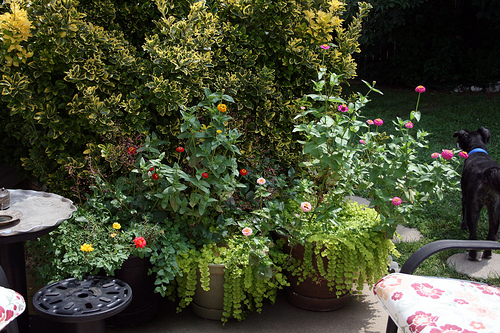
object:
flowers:
[430, 148, 469, 161]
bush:
[358, 84, 470, 239]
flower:
[133, 236, 147, 249]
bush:
[36, 184, 191, 295]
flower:
[80, 243, 95, 253]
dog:
[452, 126, 500, 261]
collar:
[467, 148, 490, 156]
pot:
[106, 254, 162, 333]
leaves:
[0, 0, 375, 174]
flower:
[410, 281, 445, 299]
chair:
[372, 237, 497, 333]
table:
[0, 189, 78, 331]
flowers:
[366, 117, 383, 125]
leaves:
[148, 228, 292, 328]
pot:
[282, 235, 355, 312]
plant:
[278, 191, 402, 302]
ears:
[452, 125, 491, 140]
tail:
[485, 167, 499, 194]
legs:
[466, 202, 500, 263]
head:
[453, 126, 492, 151]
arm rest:
[399, 238, 500, 274]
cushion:
[370, 273, 500, 333]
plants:
[0, 0, 470, 326]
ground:
[0, 279, 399, 333]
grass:
[336, 82, 500, 281]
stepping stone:
[446, 249, 500, 280]